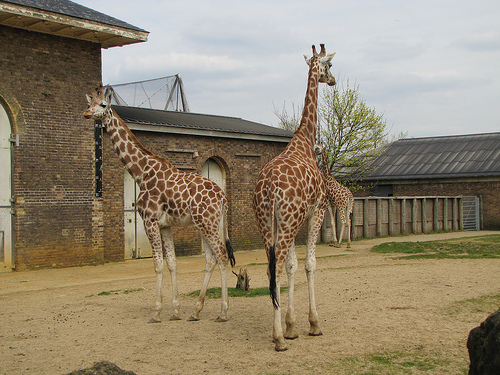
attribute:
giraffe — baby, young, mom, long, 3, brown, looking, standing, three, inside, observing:
[57, 69, 246, 334]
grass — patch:
[372, 211, 467, 273]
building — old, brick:
[110, 84, 297, 248]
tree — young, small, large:
[329, 90, 379, 146]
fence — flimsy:
[131, 65, 191, 116]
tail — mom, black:
[203, 223, 246, 286]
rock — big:
[454, 298, 496, 356]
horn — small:
[80, 84, 111, 105]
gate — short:
[434, 188, 484, 267]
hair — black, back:
[266, 255, 274, 290]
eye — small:
[97, 100, 110, 115]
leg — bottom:
[123, 225, 188, 347]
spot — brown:
[161, 184, 200, 220]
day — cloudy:
[201, 6, 271, 79]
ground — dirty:
[26, 274, 103, 323]